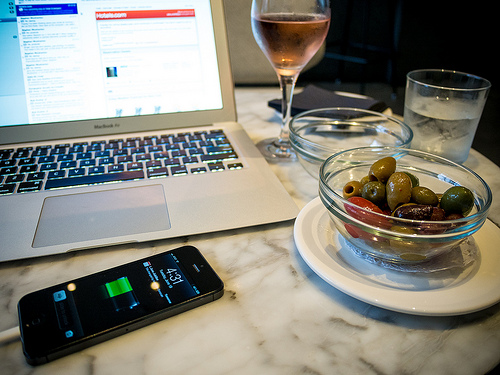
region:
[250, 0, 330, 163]
wine glass with wine in it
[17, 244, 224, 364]
black Apple iPhone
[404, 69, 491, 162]
clear glass with ice water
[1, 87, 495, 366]
white granite table top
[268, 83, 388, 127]
stack of black napkins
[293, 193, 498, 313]
small white plate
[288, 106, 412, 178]
empty clear glass bowl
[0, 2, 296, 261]
open white lap top computer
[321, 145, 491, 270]
bowl of green olives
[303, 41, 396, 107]
black arms of chair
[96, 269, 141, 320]
battery with green bar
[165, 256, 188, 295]
time is 4:31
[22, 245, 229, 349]
iPhone is charging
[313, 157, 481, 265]
clear bowl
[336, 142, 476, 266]
clear bowl of fruit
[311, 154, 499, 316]
clear bowl of fruit on a white plate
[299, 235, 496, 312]
circular shaped white plate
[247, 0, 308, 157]
clear glass of wine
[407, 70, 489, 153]
clear glass of water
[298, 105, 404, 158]
empty clear glass dish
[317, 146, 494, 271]
a glass bowl full of olives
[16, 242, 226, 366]
a black cell phone on the battery charge screen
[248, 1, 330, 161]
a glass half-full of wine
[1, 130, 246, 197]
keyboard of a laptop computer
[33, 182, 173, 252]
touchpad of a sliver laptop computer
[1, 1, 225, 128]
screen of a silver laptop computer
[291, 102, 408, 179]
an empty bowl made of glass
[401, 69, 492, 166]
a glass that is filled halfway with water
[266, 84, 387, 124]
a black napkin on a table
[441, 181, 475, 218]
a green olive in a glass bowl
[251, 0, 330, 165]
A glass of wine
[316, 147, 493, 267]
A bowl of green olives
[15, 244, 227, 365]
a cell phone that is charging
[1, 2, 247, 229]
laptop computer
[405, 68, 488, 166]
a glass of water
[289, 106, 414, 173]
an empty bowl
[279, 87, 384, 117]
a stack of black napkins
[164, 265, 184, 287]
The time is 4:31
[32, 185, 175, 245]
a mouse pad for a laptop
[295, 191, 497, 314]
a white plate holding a bowl of olives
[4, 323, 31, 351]
the battery cable for the phone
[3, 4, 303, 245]
the laptop computer on the table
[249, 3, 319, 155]
the glass of wine on the table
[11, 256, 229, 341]
the phone on the counter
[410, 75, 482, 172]
the glass of water on the counter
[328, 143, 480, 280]
the bowl of olives on the table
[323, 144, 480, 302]
the bowl and plate on the table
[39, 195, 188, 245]
the scroll pad on the laptop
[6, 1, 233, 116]
the monitor screen on the laptop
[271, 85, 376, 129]
the black napkin on the counter